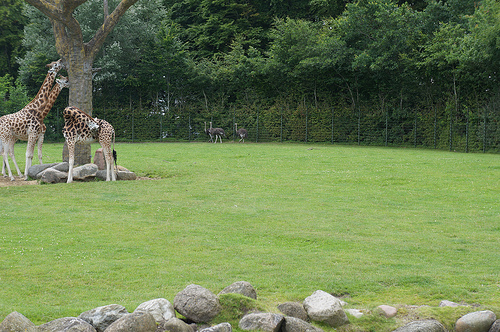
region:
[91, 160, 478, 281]
a large level grassy area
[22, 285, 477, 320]
large stones border the grass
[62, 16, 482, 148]
tall trees grow outside the fence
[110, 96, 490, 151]
ostriches near the curved fencing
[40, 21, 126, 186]
one tall tree in the grassy area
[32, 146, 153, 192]
large stones circle the tree base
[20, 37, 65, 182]
two giraffes reach up into the tree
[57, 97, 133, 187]
a giraffe bends to touch her side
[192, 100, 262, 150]
the ostriches walk in the same direction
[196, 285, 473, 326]
some rocks covered in moss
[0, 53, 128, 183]
three giraffes near a tree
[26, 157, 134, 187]
large rocks around tree's base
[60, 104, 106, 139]
giraffe with its head bent back and to the left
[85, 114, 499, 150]
dark chain-link fence at a distance from giraffes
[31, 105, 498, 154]
row of shrubs near fence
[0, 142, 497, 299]
large area with well-trimmed grass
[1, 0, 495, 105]
several trees near fence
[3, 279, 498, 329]
gathering of large stones in foreground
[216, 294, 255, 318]
green moss on large stone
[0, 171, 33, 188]
bare brown patch of ground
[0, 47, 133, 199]
giraffes around a tree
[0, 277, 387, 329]
large rocks on grass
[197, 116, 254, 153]
ostriches near fence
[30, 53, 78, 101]
giraffes eating follage on tree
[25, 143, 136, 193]
large rocks around tree trunk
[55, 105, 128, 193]
giraffe cleaning himself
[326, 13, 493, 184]
fence and trees at zoo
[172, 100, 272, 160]
ostriches running in zoo yard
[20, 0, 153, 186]
large tree in grassy area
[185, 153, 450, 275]
green grassy area of parkland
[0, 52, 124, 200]
THREE GIRAFFES STANDING UNDER TREE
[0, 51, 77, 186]
TWO GIRAFFES STANDING STRAIGHT UP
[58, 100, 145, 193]
GIRAFFE WITH HEAD BENT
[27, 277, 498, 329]
PILE OF BIG ROCKS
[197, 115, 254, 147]
THREE OSTRICHES STANDING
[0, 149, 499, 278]
GREEN GRASS ON GROUND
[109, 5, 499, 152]
FENCE AROUND THE FIELD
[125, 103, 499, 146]
GREEN TREE BUSH AROUND FENCE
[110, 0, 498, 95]
LOTS OF GREEN TREES ALONG FENCE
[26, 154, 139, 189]
PILE OF ROCKS NEAR GIRAFFES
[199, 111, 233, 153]
large bird walking on grass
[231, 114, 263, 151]
small bird walking behind large bird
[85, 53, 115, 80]
branch jutting out of large tree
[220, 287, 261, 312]
small grassy mound on ground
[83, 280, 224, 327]
cluster of large gray rocks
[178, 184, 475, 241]
well manicured green lawn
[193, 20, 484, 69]
cluster of large green trees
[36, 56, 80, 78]
giraffe eating from tree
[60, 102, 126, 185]
giraffe scratching his body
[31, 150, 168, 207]
piles of large rock around tree